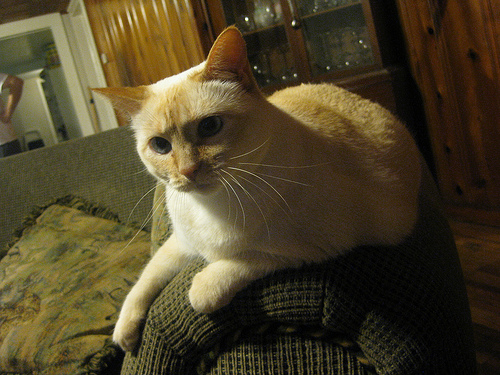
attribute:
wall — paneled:
[106, 17, 491, 207]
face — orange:
[137, 104, 235, 196]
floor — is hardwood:
[457, 187, 488, 262]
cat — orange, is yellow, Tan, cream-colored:
[82, 22, 427, 353]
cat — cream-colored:
[64, 65, 447, 331]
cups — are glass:
[240, 3, 375, 83]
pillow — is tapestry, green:
[0, 191, 153, 373]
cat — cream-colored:
[66, 20, 456, 345]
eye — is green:
[144, 128, 177, 160]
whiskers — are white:
[96, 135, 336, 255]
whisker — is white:
[229, 165, 296, 215]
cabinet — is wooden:
[82, 2, 440, 197]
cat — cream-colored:
[92, 22, 422, 303]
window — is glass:
[231, 8, 386, 75]